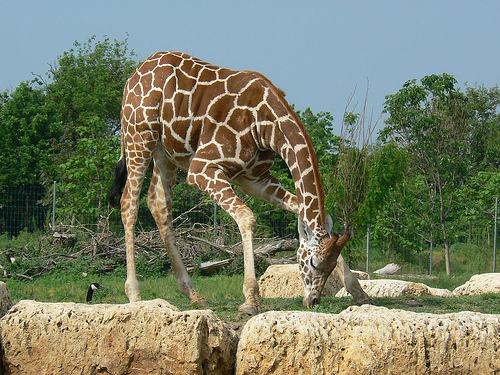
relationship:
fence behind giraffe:
[21, 198, 475, 282] [120, 52, 348, 316]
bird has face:
[86, 282, 105, 301] [89, 278, 102, 291]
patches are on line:
[167, 90, 190, 119] [185, 87, 197, 140]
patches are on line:
[169, 117, 190, 138] [185, 87, 197, 140]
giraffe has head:
[120, 52, 348, 312] [293, 229, 348, 309]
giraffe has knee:
[120, 52, 348, 316] [240, 202, 259, 240]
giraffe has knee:
[120, 52, 348, 316] [323, 205, 333, 241]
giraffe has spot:
[120, 52, 348, 316] [215, 123, 242, 160]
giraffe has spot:
[120, 52, 348, 316] [234, 79, 266, 108]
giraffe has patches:
[120, 52, 348, 316] [167, 90, 190, 119]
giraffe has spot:
[120, 52, 348, 316] [151, 67, 172, 88]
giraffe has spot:
[120, 52, 348, 316] [125, 90, 144, 110]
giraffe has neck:
[120, 52, 348, 316] [279, 101, 327, 228]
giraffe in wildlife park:
[120, 52, 348, 316] [5, 34, 498, 372]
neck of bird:
[85, 289, 95, 303] [80, 283, 106, 303]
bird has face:
[84, 279, 106, 304] [90, 284, 107, 293]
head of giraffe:
[291, 240, 360, 304] [120, 52, 348, 316]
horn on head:
[318, 234, 340, 254] [291, 240, 360, 304]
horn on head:
[336, 234, 350, 249] [291, 240, 360, 304]